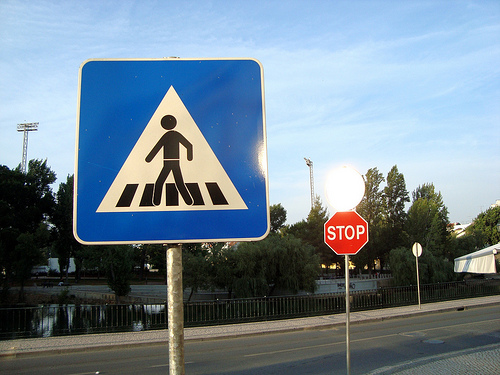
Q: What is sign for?
A: Pedestrian crosswalk.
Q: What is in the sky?
A: Clouds.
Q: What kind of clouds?
A: High streak.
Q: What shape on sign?
A: Triangle.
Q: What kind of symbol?
A: Crosswalk.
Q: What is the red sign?
A: A stop sign.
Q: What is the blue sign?
A: A pedestrian walk sign.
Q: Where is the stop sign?
A: Behind the blue one.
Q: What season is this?
A: Summer.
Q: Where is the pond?
A: Behind the road.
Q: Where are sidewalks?
A: On both sides of the road.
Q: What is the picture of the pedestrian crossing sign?
A: A person walking on a crossing strip.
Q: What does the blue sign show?
A: A pedestrian and crosswalk.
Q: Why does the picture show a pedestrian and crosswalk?
A: To indicate a crosswalk is coming.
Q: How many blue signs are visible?
A: One.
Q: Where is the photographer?
A: In front of the blue sign.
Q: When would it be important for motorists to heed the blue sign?
A: When they are moving too fast for pedestrians.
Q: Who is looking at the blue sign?
A: The photographer.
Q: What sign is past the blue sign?
A: A stop sign.